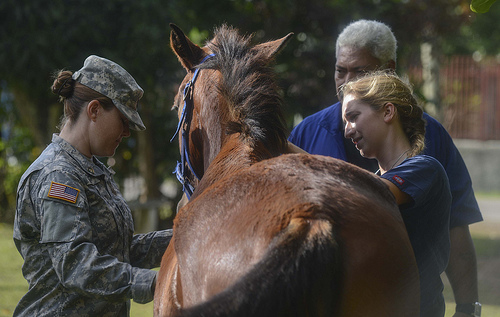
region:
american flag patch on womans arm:
[43, 173, 87, 207]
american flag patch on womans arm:
[36, 167, 98, 221]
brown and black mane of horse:
[221, 33, 280, 159]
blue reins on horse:
[175, 74, 212, 219]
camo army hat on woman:
[73, 51, 169, 129]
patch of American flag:
[46, 185, 88, 212]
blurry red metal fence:
[423, 46, 489, 129]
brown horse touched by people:
[152, 52, 347, 263]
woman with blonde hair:
[332, 86, 484, 160]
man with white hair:
[327, 18, 442, 145]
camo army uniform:
[25, 131, 114, 296]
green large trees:
[39, 17, 169, 53]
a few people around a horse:
[17, 15, 477, 280]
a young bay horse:
[130, 15, 436, 303]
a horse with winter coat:
[143, 15, 402, 290]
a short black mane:
[198, 16, 296, 157]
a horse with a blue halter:
[133, 14, 290, 216]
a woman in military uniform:
[18, 25, 185, 315]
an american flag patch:
[41, 175, 94, 207]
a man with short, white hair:
[291, 16, 474, 181]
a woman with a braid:
[333, 65, 443, 193]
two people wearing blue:
[289, 22, 495, 312]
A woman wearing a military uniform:
[9, 40, 144, 314]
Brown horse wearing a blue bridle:
[154, 15, 425, 315]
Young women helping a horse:
[321, 77, 458, 315]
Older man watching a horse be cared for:
[302, 14, 482, 314]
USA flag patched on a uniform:
[36, 171, 91, 209]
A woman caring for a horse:
[35, 38, 150, 313]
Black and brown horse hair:
[151, 16, 303, 158]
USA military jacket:
[14, 122, 146, 314]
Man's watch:
[441, 280, 493, 314]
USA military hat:
[51, 43, 150, 127]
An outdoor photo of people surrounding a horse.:
[1, 0, 498, 315]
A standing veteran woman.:
[1, 55, 158, 313]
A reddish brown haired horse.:
[153, 26, 419, 315]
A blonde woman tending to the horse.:
[338, 73, 462, 314]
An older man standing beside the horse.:
[291, 13, 491, 156]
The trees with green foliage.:
[1, 0, 172, 53]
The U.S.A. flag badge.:
[43, 178, 80, 202]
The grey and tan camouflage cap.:
[71, 52, 145, 129]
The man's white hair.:
[337, 21, 401, 54]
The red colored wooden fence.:
[440, 55, 499, 138]